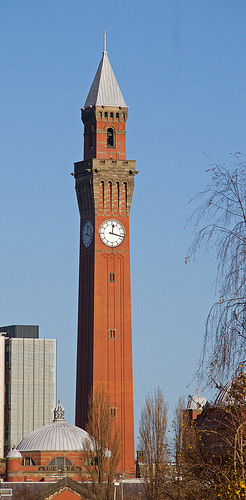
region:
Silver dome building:
[18, 399, 94, 462]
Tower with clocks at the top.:
[73, 42, 139, 440]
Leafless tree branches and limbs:
[198, 149, 233, 330]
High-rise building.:
[10, 337, 60, 424]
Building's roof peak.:
[41, 475, 98, 497]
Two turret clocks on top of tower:
[75, 204, 138, 249]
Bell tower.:
[76, 24, 130, 157]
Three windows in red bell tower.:
[72, 260, 134, 419]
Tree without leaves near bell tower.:
[134, 383, 174, 492]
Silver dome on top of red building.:
[179, 387, 211, 412]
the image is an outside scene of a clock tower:
[0, 0, 245, 499]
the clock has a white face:
[98, 218, 125, 246]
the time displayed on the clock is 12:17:
[98, 218, 125, 246]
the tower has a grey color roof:
[82, 28, 122, 102]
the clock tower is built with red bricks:
[71, 29, 138, 479]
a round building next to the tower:
[4, 396, 107, 477]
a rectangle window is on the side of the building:
[106, 327, 115, 336]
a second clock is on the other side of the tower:
[79, 217, 91, 247]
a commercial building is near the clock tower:
[0, 323, 55, 443]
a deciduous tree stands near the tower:
[138, 383, 172, 498]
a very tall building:
[74, 26, 146, 498]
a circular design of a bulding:
[21, 400, 101, 481]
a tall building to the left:
[0, 319, 62, 479]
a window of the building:
[106, 407, 117, 414]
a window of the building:
[107, 327, 122, 340]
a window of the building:
[106, 272, 118, 283]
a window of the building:
[103, 124, 117, 151]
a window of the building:
[21, 456, 39, 469]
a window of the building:
[46, 456, 74, 470]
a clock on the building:
[96, 213, 125, 249]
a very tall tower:
[43, 0, 175, 499]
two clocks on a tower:
[75, 212, 129, 254]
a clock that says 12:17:
[94, 215, 134, 253]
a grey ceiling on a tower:
[52, 9, 140, 118]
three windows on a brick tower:
[103, 257, 128, 437]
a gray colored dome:
[13, 394, 108, 477]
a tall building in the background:
[0, 314, 72, 457]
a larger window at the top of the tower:
[100, 122, 120, 158]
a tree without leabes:
[187, 154, 244, 431]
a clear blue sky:
[127, 12, 238, 396]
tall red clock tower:
[67, 141, 137, 366]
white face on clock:
[95, 213, 128, 255]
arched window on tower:
[102, 122, 121, 152]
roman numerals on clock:
[100, 222, 125, 247]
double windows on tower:
[106, 264, 116, 286]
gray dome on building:
[19, 419, 98, 462]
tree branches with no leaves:
[193, 204, 237, 239]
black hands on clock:
[105, 223, 123, 240]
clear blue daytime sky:
[151, 294, 197, 352]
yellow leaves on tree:
[217, 475, 241, 493]